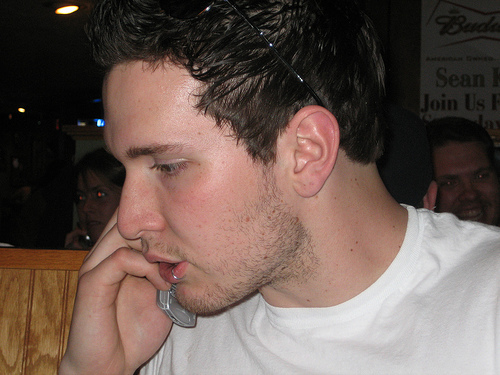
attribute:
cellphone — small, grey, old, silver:
[153, 287, 200, 329]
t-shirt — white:
[122, 198, 500, 373]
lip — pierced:
[156, 263, 190, 281]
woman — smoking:
[60, 154, 134, 255]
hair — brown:
[69, 147, 130, 200]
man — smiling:
[426, 114, 500, 230]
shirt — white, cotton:
[124, 200, 498, 374]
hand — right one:
[68, 208, 182, 374]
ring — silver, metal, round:
[168, 267, 181, 283]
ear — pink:
[284, 103, 344, 200]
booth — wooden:
[3, 249, 105, 373]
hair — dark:
[80, 1, 393, 169]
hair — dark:
[426, 115, 500, 171]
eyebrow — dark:
[127, 143, 199, 156]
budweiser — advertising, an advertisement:
[423, 1, 500, 54]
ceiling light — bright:
[50, 0, 86, 18]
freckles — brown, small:
[236, 206, 282, 226]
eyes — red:
[72, 183, 114, 210]